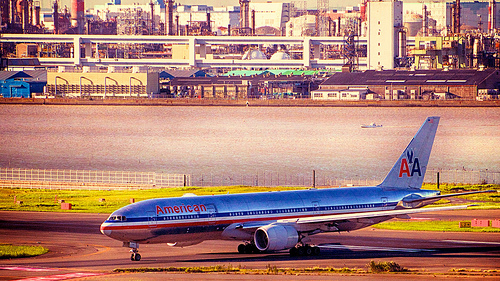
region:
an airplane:
[91, 115, 434, 247]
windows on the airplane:
[161, 213, 211, 223]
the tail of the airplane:
[390, 133, 436, 192]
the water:
[9, 103, 360, 163]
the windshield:
[106, 215, 127, 224]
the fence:
[28, 172, 156, 189]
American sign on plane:
[152, 202, 213, 215]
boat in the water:
[356, 119, 388, 130]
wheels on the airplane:
[294, 243, 321, 256]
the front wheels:
[126, 249, 145, 259]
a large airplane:
[97, 113, 498, 262]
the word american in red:
[153, 194, 208, 224]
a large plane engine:
[253, 218, 303, 250]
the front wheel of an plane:
[127, 242, 141, 262]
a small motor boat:
[358, 120, 385, 130]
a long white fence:
[1, 164, 499, 188]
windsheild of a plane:
[107, 213, 126, 223]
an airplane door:
[145, 211, 160, 228]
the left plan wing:
[284, 202, 468, 225]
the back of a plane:
[349, 108, 479, 235]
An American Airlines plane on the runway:
[101, 109, 488, 250]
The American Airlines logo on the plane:
[148, 202, 210, 214]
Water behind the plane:
[78, 112, 325, 158]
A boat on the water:
[360, 120, 383, 128]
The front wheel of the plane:
[124, 247, 145, 262]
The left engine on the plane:
[253, 222, 302, 252]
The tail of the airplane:
[391, 112, 438, 189]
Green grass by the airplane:
[41, 190, 129, 205]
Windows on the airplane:
[225, 203, 292, 215]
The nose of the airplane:
[97, 218, 115, 238]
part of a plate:
[367, 200, 377, 206]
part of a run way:
[166, 258, 181, 267]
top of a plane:
[165, 198, 171, 210]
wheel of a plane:
[126, 253, 144, 260]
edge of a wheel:
[310, 241, 330, 259]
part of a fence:
[128, 179, 137, 180]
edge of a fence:
[103, 158, 120, 187]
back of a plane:
[366, 188, 373, 189]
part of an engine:
[266, 227, 278, 243]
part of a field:
[461, 223, 485, 235]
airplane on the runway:
[92, 109, 487, 269]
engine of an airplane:
[250, 219, 301, 254]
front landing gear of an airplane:
[122, 242, 147, 263]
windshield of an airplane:
[106, 210, 124, 222]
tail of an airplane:
[373, 112, 447, 190]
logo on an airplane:
[393, 148, 425, 183]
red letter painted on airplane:
[151, 201, 166, 216]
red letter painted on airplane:
[164, 203, 174, 217]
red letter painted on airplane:
[199, 202, 207, 214]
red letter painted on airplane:
[170, 203, 180, 215]